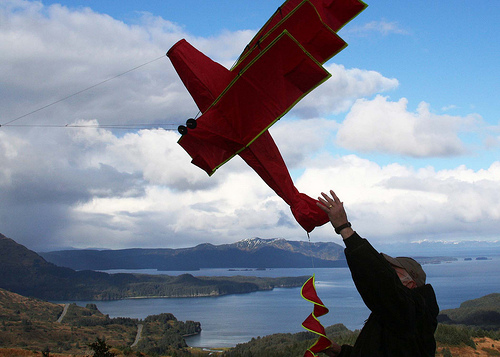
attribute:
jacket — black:
[341, 230, 438, 350]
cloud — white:
[357, 106, 457, 155]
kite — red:
[143, 7, 355, 234]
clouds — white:
[4, 34, 159, 221]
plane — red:
[133, 8, 373, 243]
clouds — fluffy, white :
[306, 117, 456, 231]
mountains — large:
[37, 236, 456, 268]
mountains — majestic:
[38, 234, 342, 266]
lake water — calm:
[186, 290, 310, 329]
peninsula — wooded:
[0, 239, 319, 301]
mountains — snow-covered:
[8, 225, 342, 355]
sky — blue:
[426, 43, 475, 98]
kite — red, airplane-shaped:
[160, 4, 394, 247]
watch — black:
[334, 221, 352, 233]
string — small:
[0, 109, 174, 139]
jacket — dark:
[379, 289, 429, 348]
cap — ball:
[399, 256, 419, 263]